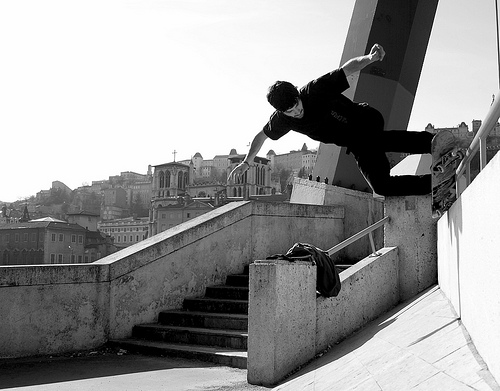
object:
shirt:
[262, 69, 358, 150]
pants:
[352, 109, 435, 197]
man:
[227, 41, 434, 201]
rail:
[427, 93, 499, 200]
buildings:
[0, 159, 154, 220]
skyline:
[0, 117, 500, 204]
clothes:
[270, 236, 344, 300]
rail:
[318, 212, 388, 255]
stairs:
[117, 223, 388, 361]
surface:
[29, 351, 425, 383]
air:
[397, 218, 465, 308]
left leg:
[340, 144, 431, 196]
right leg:
[383, 129, 433, 154]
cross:
[168, 145, 178, 165]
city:
[0, 0, 500, 391]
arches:
[158, 171, 188, 198]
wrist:
[238, 156, 251, 171]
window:
[45, 231, 55, 247]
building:
[0, 214, 92, 268]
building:
[152, 144, 187, 207]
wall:
[436, 143, 500, 387]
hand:
[366, 43, 383, 67]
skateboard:
[425, 123, 468, 218]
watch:
[240, 158, 250, 174]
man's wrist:
[234, 152, 252, 169]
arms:
[224, 111, 291, 184]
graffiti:
[430, 138, 456, 219]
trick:
[259, 68, 432, 198]